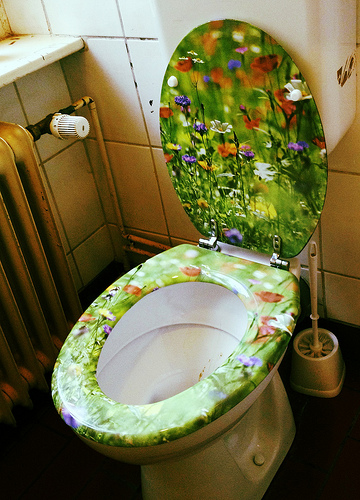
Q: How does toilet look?
A: Worn.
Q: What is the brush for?
A: Toilet.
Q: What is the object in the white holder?
A: Toilet brush.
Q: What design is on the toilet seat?
A: Flowers.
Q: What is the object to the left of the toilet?
A: Furnace.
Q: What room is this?
A: Bathroom.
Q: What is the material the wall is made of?
A: Tile.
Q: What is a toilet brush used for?
A: Clean the toilet.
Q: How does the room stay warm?
A: Furnace.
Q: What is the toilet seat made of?
A: Foam.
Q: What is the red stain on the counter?
A: Rust.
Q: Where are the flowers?
A: On the toilet seat.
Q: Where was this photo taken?
A: In a bathroom.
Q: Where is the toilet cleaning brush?
A: On the floor.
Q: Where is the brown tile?
A: On the floor.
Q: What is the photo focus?
A: Toilet.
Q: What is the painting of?
A: Flowers.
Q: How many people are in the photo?
A: 0.